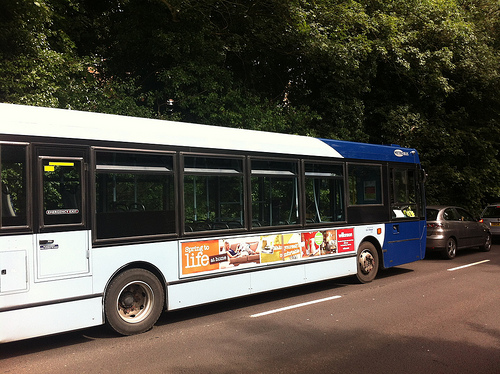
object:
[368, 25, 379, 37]
leaves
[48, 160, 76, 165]
sticker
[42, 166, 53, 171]
sticker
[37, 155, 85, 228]
window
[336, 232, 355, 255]
writing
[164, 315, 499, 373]
shadows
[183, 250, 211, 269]
life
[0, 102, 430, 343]
bus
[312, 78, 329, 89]
leaves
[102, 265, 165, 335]
tire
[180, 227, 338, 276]
sign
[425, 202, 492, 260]
vehicles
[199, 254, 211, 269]
lettering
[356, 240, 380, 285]
tire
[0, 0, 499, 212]
trees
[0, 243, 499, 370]
road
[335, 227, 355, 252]
sign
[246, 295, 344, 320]
stripes